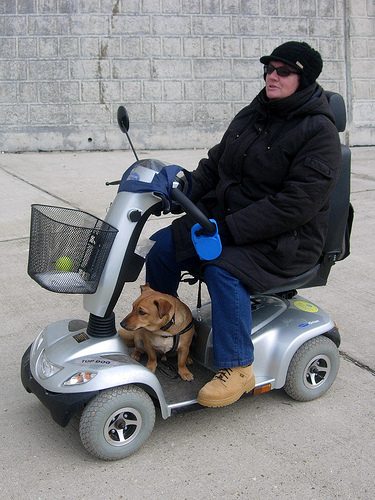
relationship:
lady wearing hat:
[127, 42, 340, 430] [263, 41, 322, 86]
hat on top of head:
[263, 41, 322, 86] [259, 41, 319, 107]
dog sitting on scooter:
[122, 295, 206, 381] [14, 167, 344, 442]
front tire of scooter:
[74, 388, 163, 461] [14, 167, 344, 442]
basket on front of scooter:
[20, 203, 118, 295] [14, 167, 344, 442]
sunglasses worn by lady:
[259, 61, 303, 82] [127, 42, 340, 430]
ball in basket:
[57, 254, 77, 272] [20, 203, 118, 295]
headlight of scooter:
[33, 353, 86, 383] [14, 167, 344, 442]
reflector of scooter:
[250, 386, 278, 393] [14, 167, 344, 442]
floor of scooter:
[152, 356, 218, 401] [14, 167, 344, 442]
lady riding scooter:
[127, 42, 340, 430] [14, 167, 344, 442]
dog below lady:
[122, 295, 206, 381] [127, 42, 340, 430]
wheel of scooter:
[74, 388, 163, 461] [14, 167, 344, 442]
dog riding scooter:
[122, 295, 206, 381] [14, 167, 344, 442]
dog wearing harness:
[122, 295, 206, 381] [151, 327, 198, 357]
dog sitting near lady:
[122, 295, 206, 381] [127, 42, 340, 430]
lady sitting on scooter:
[127, 42, 340, 430] [14, 167, 344, 442]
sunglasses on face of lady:
[259, 61, 303, 82] [127, 42, 340, 430]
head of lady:
[259, 41, 319, 107] [127, 42, 340, 430]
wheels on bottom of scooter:
[74, 340, 340, 456] [14, 167, 344, 442]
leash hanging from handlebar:
[189, 220, 223, 268] [167, 191, 220, 240]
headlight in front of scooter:
[33, 353, 86, 383] [14, 167, 344, 442]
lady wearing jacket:
[127, 42, 340, 430] [180, 86, 338, 286]